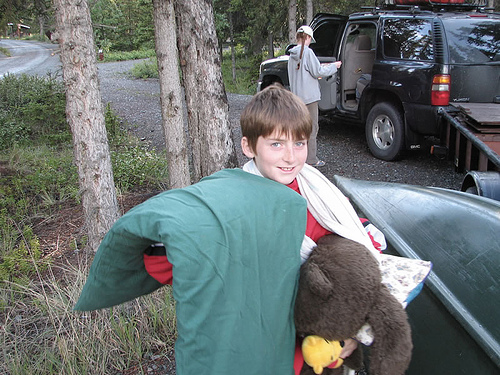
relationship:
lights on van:
[428, 62, 455, 107] [255, 2, 500, 164]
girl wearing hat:
[287, 24, 343, 167] [293, 12, 319, 37]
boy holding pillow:
[150, 87, 379, 372] [72, 166, 308, 373]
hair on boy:
[240, 82, 316, 157] [150, 87, 379, 372]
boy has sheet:
[140, 83, 389, 375] [299, 162, 392, 262]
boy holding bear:
[140, 83, 389, 375] [290, 233, 414, 375]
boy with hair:
[140, 83, 389, 375] [240, 85, 313, 156]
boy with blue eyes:
[140, 83, 389, 375] [267, 136, 305, 151]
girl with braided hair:
[287, 24, 343, 167] [294, 32, 307, 71]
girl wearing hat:
[287, 24, 343, 167] [296, 22, 317, 42]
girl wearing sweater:
[267, 12, 353, 187] [275, 25, 348, 114]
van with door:
[257, 2, 497, 164] [304, 10, 350, 115]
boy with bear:
[140, 83, 389, 375] [304, 246, 396, 374]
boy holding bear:
[140, 83, 389, 375] [292, 222, 417, 367]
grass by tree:
[16, 238, 103, 363] [56, 7, 125, 255]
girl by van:
[287, 24, 343, 167] [255, 2, 500, 164]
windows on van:
[382, 17, 498, 62] [255, 2, 500, 164]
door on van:
[301, 16, 348, 118] [255, 2, 500, 164]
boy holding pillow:
[150, 87, 379, 372] [162, 188, 293, 364]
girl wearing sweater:
[287, 24, 343, 167] [285, 43, 337, 106]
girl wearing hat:
[287, 24, 343, 167] [284, 14, 316, 56]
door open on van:
[308, 11, 348, 113] [255, 2, 500, 164]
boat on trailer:
[331, 171, 498, 373] [440, 93, 499, 198]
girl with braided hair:
[287, 24, 343, 167] [294, 28, 308, 73]